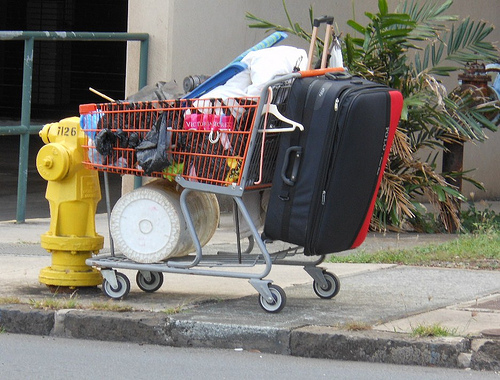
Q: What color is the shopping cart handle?
A: Orange.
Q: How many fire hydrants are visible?
A: One.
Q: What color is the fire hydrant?
A: Yellow.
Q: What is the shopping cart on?
A: Sidewalk.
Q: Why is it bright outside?
A: It's daytime.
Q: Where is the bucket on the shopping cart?
A: Bottom rack.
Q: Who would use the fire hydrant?
A: Firefighters.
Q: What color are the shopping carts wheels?
A: Black.